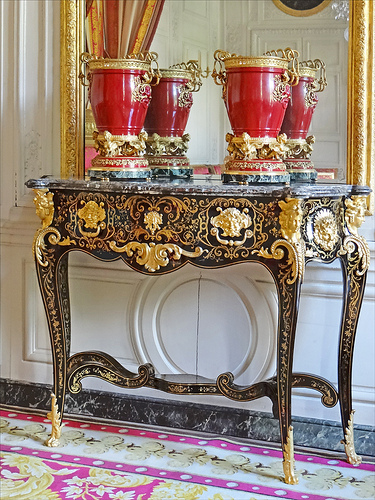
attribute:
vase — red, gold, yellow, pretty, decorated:
[82, 61, 153, 149]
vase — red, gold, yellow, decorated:
[215, 51, 296, 165]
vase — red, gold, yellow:
[298, 57, 319, 151]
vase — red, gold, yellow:
[153, 64, 197, 163]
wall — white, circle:
[168, 306, 227, 347]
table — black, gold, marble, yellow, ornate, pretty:
[27, 181, 350, 475]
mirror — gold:
[66, 8, 82, 57]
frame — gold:
[49, 14, 79, 72]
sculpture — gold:
[72, 197, 108, 231]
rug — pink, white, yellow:
[87, 451, 161, 491]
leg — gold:
[272, 421, 301, 476]